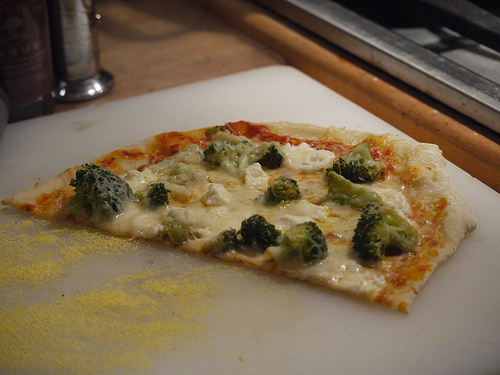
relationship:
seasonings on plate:
[3, 212, 221, 374] [2, 64, 499, 374]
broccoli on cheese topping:
[71, 124, 414, 274] [0, 120, 478, 314]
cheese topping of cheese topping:
[81, 138, 412, 302] [0, 120, 478, 314]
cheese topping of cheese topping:
[0, 120, 478, 314] [0, 120, 478, 314]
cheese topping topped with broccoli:
[0, 120, 478, 314] [71, 124, 414, 274]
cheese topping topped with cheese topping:
[0, 120, 478, 314] [81, 138, 412, 302]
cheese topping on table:
[0, 120, 478, 314] [5, 2, 499, 367]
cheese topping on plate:
[0, 120, 478, 314] [2, 64, 499, 374]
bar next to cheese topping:
[291, 1, 500, 115] [0, 120, 478, 314]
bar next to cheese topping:
[217, 6, 494, 157] [0, 120, 478, 314]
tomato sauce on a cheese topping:
[161, 111, 386, 160] [0, 120, 478, 314]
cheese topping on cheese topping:
[81, 138, 412, 302] [0, 120, 478, 314]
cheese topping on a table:
[0, 120, 478, 314] [5, 2, 499, 367]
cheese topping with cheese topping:
[0, 120, 478, 314] [81, 138, 412, 302]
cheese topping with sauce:
[0, 120, 478, 314] [102, 123, 397, 187]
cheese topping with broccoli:
[0, 120, 478, 314] [71, 124, 414, 274]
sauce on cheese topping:
[102, 123, 397, 187] [0, 120, 478, 314]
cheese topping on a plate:
[0, 120, 478, 314] [2, 64, 499, 374]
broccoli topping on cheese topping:
[71, 124, 414, 274] [0, 120, 478, 314]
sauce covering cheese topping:
[102, 123, 397, 187] [0, 120, 478, 314]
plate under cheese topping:
[2, 64, 499, 374] [0, 120, 478, 314]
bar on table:
[217, 6, 494, 157] [5, 2, 499, 367]